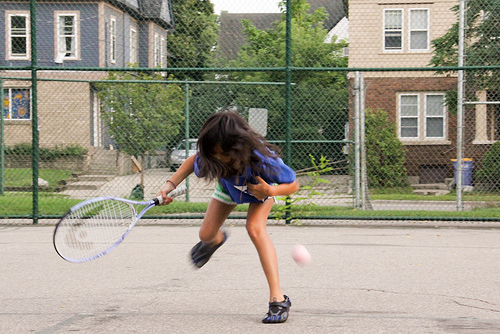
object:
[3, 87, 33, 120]
fabric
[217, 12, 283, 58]
roof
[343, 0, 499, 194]
house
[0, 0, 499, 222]
fence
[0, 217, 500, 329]
ground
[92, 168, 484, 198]
street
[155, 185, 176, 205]
hand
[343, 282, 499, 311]
line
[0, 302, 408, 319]
line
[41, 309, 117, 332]
crack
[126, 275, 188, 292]
crack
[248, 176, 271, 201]
hand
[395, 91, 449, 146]
window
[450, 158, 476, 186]
can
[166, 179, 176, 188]
tie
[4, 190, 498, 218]
grass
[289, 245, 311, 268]
ball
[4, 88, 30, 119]
decorative curtain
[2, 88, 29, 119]
window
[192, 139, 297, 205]
shirt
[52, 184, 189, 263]
racket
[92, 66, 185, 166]
tree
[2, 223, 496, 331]
floor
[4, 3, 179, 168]
house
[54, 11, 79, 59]
window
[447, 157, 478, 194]
garbage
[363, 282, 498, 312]
crack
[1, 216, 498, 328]
pavement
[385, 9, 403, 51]
windows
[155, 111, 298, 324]
girl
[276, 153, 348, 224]
weed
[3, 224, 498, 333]
tennis court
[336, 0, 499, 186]
building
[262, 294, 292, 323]
foot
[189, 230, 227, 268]
foot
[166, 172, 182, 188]
wrist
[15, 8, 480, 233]
chain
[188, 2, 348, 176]
house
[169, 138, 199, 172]
car